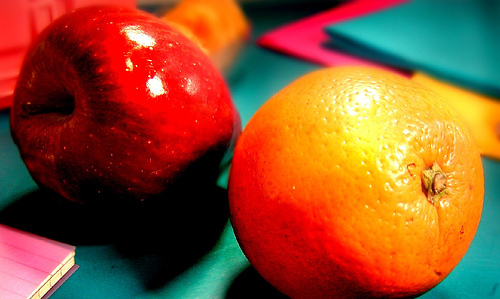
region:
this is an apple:
[6, 12, 248, 242]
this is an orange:
[222, 17, 488, 289]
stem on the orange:
[406, 148, 465, 212]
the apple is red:
[4, 6, 232, 234]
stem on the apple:
[8, 84, 77, 136]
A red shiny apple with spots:
[13, 8, 233, 218]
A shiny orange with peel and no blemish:
[233, 63, 490, 288]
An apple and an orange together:
[9, 8, 480, 297]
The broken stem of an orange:
[413, 160, 454, 203]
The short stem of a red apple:
[21, 83, 85, 133]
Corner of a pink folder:
[261, 10, 321, 58]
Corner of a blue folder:
[326, 20, 400, 59]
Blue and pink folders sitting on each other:
[263, 12, 376, 64]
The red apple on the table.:
[10, 13, 231, 215]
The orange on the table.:
[230, 62, 492, 297]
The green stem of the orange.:
[415, 163, 449, 195]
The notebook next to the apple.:
[0, 223, 81, 294]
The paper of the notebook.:
[26, 255, 81, 297]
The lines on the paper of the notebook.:
[3, 233, 71, 297]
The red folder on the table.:
[263, 0, 418, 82]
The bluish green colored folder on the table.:
[320, 2, 498, 86]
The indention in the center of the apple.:
[37, 89, 81, 116]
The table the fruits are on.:
[2, 10, 489, 295]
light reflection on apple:
[145, 73, 168, 100]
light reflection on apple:
[124, 57, 136, 72]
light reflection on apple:
[122, 23, 157, 52]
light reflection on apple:
[180, 71, 197, 93]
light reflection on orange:
[326, 75, 385, 121]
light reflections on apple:
[117, 20, 195, 100]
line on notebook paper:
[1, 238, 60, 268]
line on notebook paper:
[1, 250, 49, 274]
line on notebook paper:
[1, 267, 38, 287]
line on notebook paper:
[1, 283, 28, 297]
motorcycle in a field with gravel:
[282, 249, 337, 278]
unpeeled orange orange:
[232, 64, 482, 297]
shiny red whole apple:
[9, 3, 243, 211]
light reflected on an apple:
[115, 15, 202, 104]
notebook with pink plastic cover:
[1, 218, 80, 297]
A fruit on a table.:
[33, 24, 198, 226]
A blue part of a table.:
[86, 206, 206, 287]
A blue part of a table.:
[228, 46, 281, 86]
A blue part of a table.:
[138, 2, 169, 17]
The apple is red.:
[8, 5, 235, 217]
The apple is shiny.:
[1, 7, 233, 224]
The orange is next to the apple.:
[222, 55, 483, 295]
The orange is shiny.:
[231, 50, 488, 297]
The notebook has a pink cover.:
[1, 213, 74, 297]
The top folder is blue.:
[324, 5, 498, 97]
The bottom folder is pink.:
[257, 0, 409, 70]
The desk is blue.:
[1, 3, 497, 297]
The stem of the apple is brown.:
[17, 93, 72, 118]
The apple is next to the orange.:
[13, 2, 230, 212]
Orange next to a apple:
[231, 62, 467, 287]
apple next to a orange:
[5, 5, 230, 231]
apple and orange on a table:
[9, 2, 492, 284]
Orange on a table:
[223, 60, 497, 297]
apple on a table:
[8, 5, 243, 235]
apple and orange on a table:
[0, 0, 488, 288]